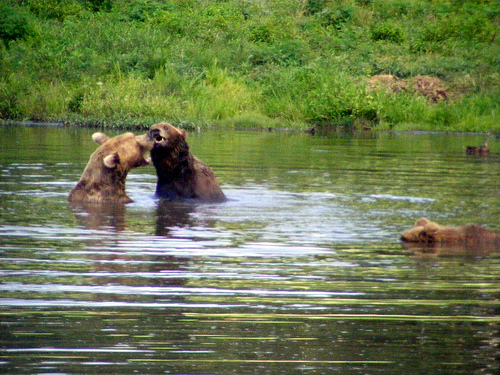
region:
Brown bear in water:
[57, 122, 157, 276]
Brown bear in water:
[145, 110, 232, 220]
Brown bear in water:
[379, 203, 494, 283]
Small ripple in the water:
[2, 299, 63, 349]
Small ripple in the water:
[69, 315, 104, 372]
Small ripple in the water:
[108, 280, 190, 367]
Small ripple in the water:
[202, 243, 288, 322]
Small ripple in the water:
[334, 287, 399, 353]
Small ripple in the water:
[298, 156, 390, 212]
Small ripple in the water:
[446, 162, 491, 216]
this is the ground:
[177, 13, 257, 59]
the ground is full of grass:
[187, 15, 289, 59]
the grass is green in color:
[226, 36, 301, 92]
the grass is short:
[219, 33, 316, 97]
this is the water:
[113, 248, 251, 326]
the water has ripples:
[86, 223, 311, 296]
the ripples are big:
[84, 243, 218, 295]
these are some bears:
[68, 113, 245, 218]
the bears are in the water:
[53, 120, 233, 206]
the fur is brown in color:
[111, 142, 118, 144]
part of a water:
[271, 210, 288, 237]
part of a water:
[285, 234, 318, 279]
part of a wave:
[249, 246, 302, 305]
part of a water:
[296, 253, 344, 315]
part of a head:
[416, 226, 422, 239]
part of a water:
[313, 251, 340, 279]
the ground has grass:
[218, 6, 313, 83]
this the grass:
[261, 34, 328, 76]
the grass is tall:
[180, 40, 252, 100]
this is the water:
[176, 316, 275, 359]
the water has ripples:
[108, 248, 288, 303]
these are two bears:
[72, 119, 222, 201]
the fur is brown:
[113, 136, 130, 150]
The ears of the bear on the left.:
[92, 133, 117, 166]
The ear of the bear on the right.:
[177, 126, 192, 141]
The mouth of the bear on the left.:
[144, 142, 151, 162]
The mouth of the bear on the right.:
[150, 135, 165, 142]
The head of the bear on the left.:
[93, 126, 150, 171]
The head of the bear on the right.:
[146, 120, 186, 155]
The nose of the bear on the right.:
[150, 127, 160, 132]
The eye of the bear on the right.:
[162, 120, 167, 131]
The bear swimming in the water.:
[397, 218, 494, 250]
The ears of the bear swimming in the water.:
[412, 216, 436, 234]